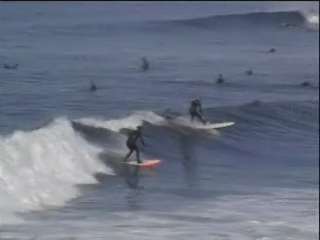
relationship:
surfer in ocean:
[120, 123, 161, 168] [1, 0, 319, 240]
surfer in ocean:
[187, 96, 237, 131] [1, 0, 319, 240]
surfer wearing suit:
[120, 123, 161, 168] [123, 128, 145, 161]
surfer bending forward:
[120, 123, 161, 168] [123, 128, 145, 161]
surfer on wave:
[120, 123, 161, 168] [0, 91, 316, 207]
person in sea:
[138, 54, 149, 71] [1, 0, 319, 240]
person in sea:
[216, 73, 224, 85] [1, 0, 319, 240]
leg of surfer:
[194, 113, 209, 126] [187, 96, 237, 131]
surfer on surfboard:
[120, 123, 161, 168] [125, 158, 161, 167]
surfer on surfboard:
[187, 96, 237, 131] [190, 120, 236, 130]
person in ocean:
[138, 54, 149, 71] [1, 0, 319, 240]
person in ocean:
[216, 73, 224, 85] [1, 0, 319, 240]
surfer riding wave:
[120, 123, 161, 168] [0, 91, 316, 207]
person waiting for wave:
[138, 54, 149, 71] [0, 91, 316, 207]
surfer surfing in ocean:
[120, 123, 161, 168] [1, 0, 319, 240]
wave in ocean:
[0, 91, 316, 207] [1, 0, 319, 240]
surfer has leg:
[187, 96, 237, 131] [194, 113, 209, 126]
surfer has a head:
[120, 123, 161, 168] [136, 124, 143, 131]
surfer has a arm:
[120, 123, 161, 168] [140, 135, 149, 149]